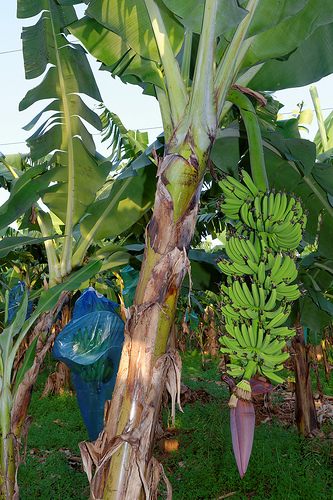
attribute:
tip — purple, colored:
[228, 398, 254, 477]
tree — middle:
[67, 2, 303, 490]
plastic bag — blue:
[71, 298, 91, 326]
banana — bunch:
[255, 321, 263, 348]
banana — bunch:
[247, 322, 255, 347]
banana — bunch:
[240, 278, 253, 305]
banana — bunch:
[257, 256, 265, 282]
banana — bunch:
[242, 255, 258, 272]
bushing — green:
[159, 394, 242, 499]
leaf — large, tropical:
[16, 1, 113, 274]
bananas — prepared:
[222, 165, 300, 400]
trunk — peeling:
[88, 138, 212, 499]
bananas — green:
[213, 169, 305, 382]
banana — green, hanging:
[182, 106, 315, 401]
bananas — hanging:
[223, 172, 309, 390]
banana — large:
[252, 194, 261, 215]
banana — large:
[249, 325, 255, 345]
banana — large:
[234, 279, 243, 299]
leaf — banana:
[2, 0, 110, 278]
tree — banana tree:
[64, 0, 331, 498]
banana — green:
[230, 190, 297, 393]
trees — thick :
[197, 308, 222, 375]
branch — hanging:
[217, 89, 300, 190]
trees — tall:
[1, 1, 331, 495]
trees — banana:
[35, 194, 307, 473]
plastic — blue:
[66, 334, 113, 406]